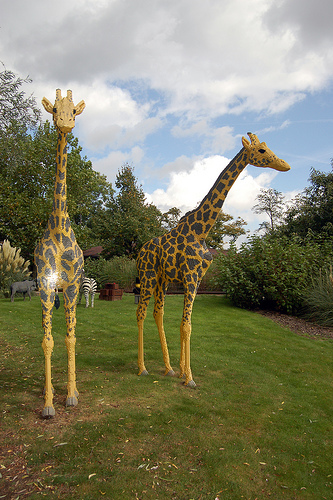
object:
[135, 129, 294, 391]
giraffe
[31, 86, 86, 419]
giraffe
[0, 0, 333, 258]
cloud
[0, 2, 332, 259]
sky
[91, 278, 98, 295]
butt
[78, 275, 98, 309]
zebra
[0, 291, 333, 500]
grass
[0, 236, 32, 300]
bush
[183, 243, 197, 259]
spot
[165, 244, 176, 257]
spot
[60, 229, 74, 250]
spot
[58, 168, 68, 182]
spot